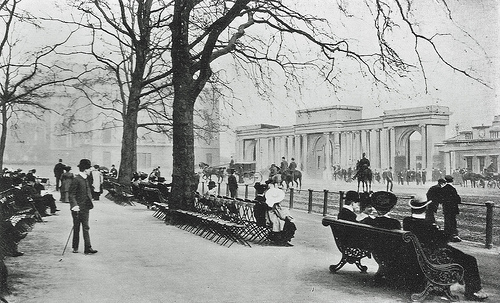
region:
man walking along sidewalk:
[61, 145, 121, 261]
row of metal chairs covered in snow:
[139, 185, 251, 257]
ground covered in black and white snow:
[129, 239, 218, 299]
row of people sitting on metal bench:
[309, 188, 469, 295]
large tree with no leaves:
[169, 0, 263, 145]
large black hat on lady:
[369, 189, 401, 217]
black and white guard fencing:
[288, 185, 329, 215]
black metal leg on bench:
[325, 255, 370, 271]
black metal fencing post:
[480, 194, 498, 249]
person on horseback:
[349, 149, 377, 189]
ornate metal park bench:
[322, 217, 467, 302]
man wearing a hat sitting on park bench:
[403, 192, 488, 302]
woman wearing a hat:
[370, 190, 402, 233]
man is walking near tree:
[55, 158, 100, 258]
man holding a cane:
[57, 156, 103, 256]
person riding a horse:
[352, 152, 373, 187]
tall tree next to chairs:
[165, 0, 495, 215]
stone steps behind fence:
[282, 183, 497, 243]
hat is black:
[72, 157, 93, 169]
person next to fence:
[441, 175, 464, 242]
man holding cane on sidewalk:
[40, 120, 165, 280]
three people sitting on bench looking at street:
[297, 179, 493, 297]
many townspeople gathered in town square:
[0, 0, 495, 299]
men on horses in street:
[170, 95, 402, 192]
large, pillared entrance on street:
[223, 49, 499, 199]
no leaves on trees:
[4, 0, 490, 241]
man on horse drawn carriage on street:
[188, 143, 264, 183]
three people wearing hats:
[316, 184, 494, 296]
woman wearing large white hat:
[259, 185, 296, 239]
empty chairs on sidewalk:
[164, 178, 256, 264]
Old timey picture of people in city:
[1, 5, 496, 265]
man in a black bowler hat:
[65, 156, 97, 255]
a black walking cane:
[62, 215, 75, 252]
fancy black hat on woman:
[368, 188, 398, 216]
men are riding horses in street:
[270, 156, 304, 190]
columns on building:
[296, 133, 338, 179]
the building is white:
[226, 118, 458, 181]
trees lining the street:
[86, 2, 243, 232]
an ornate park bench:
[318, 217, 464, 298]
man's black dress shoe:
[465, 288, 492, 302]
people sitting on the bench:
[127, 168, 451, 270]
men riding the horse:
[258, 151, 397, 193]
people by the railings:
[424, 170, 484, 250]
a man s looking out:
[55, 148, 100, 248]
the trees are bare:
[8, 9, 413, 129]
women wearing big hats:
[357, 188, 401, 225]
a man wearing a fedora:
[76, 158, 98, 168]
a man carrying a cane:
[53, 201, 89, 262]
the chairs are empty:
[176, 200, 244, 232]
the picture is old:
[8, 30, 404, 301]